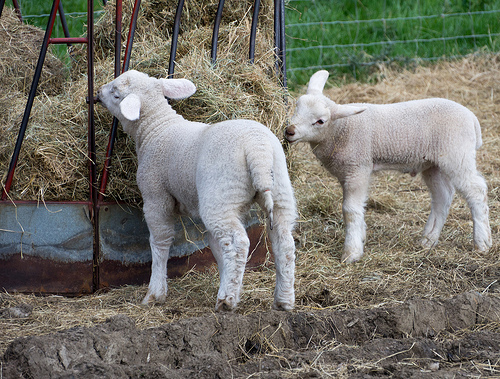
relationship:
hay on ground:
[0, 44, 499, 356] [0, 0, 499, 377]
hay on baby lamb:
[5, 1, 324, 205] [97, 69, 298, 313]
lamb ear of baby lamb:
[158, 73, 200, 105] [97, 69, 298, 313]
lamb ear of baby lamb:
[113, 88, 143, 125] [97, 69, 298, 313]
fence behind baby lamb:
[0, 7, 496, 72] [97, 69, 298, 313]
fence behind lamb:
[0, 7, 496, 72] [285, 69, 493, 261]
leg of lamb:
[340, 167, 368, 264] [285, 69, 493, 261]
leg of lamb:
[142, 196, 170, 305] [285, 69, 493, 261]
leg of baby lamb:
[202, 213, 248, 309] [97, 69, 298, 313]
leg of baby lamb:
[444, 166, 491, 256] [97, 69, 298, 313]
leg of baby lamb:
[264, 204, 297, 314] [97, 69, 298, 313]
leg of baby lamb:
[142, 196, 169, 293] [97, 69, 298, 313]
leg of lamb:
[422, 193, 447, 253] [285, 69, 493, 261]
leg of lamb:
[441, 166, 491, 238] [291, 87, 488, 253]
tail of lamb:
[476, 122, 486, 150] [285, 69, 493, 261]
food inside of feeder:
[0, 0, 293, 225] [6, 2, 291, 272]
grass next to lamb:
[358, 12, 441, 47] [265, 51, 498, 265]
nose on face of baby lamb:
[93, 85, 115, 110] [97, 69, 298, 313]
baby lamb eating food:
[97, 69, 298, 313] [6, 4, 310, 225]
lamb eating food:
[285, 69, 493, 261] [6, 4, 310, 225]